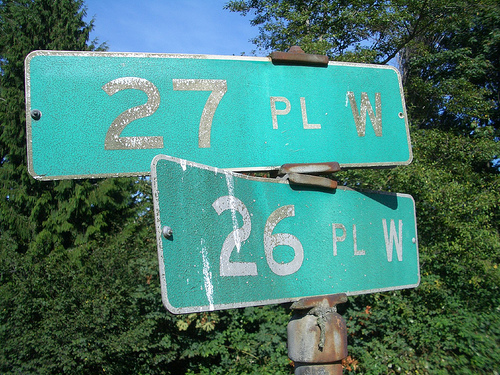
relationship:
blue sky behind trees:
[77, 2, 409, 78] [1, 2, 495, 374]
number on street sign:
[212, 192, 258, 278] [122, 152, 432, 321]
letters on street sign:
[334, 221, 402, 260] [20, 49, 421, 313]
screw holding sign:
[162, 226, 174, 242] [134, 154, 428, 311]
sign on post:
[134, 154, 428, 311] [287, 290, 348, 373]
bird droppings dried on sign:
[180, 156, 246, 315] [143, 153, 468, 289]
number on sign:
[98, 69, 228, 159] [5, 36, 420, 201]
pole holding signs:
[288, 293, 345, 374] [11, 51, 446, 312]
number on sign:
[212, 192, 262, 278] [134, 154, 428, 311]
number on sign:
[265, 204, 305, 277] [134, 154, 428, 311]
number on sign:
[212, 192, 258, 278] [134, 154, 428, 311]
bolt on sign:
[162, 225, 173, 237] [147, 154, 423, 315]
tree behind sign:
[4, 1, 151, 374] [21, 47, 414, 182]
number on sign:
[265, 203, 305, 277] [19, 47, 414, 169]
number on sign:
[212, 192, 258, 278] [151, 159, 423, 313]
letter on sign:
[295, 95, 327, 138] [20, 33, 426, 183]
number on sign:
[174, 77, 242, 150] [17, 46, 429, 182]